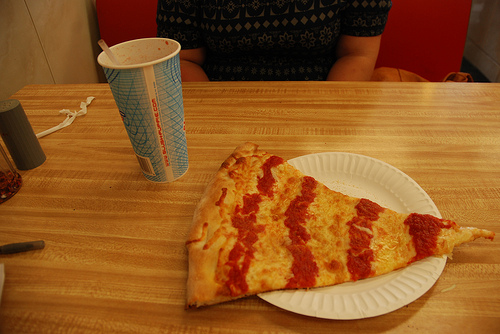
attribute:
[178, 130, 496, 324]
pizza — sliced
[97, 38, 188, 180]
cup — blue, white, paper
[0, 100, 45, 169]
pepper shaker — gray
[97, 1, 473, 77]
bench — red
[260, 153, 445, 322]
plate — paper, white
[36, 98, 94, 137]
straw paper — white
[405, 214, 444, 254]
sauce — red